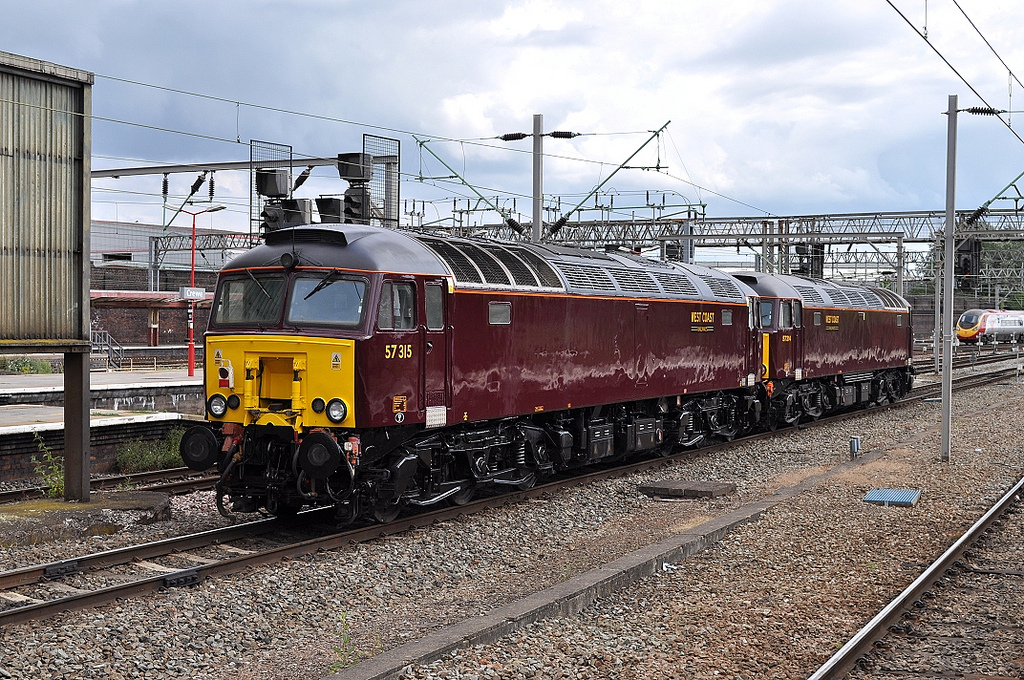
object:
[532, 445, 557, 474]
wheel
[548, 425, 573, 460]
wheel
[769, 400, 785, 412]
wheel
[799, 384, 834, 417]
wheel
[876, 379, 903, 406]
wheel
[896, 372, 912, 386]
wheel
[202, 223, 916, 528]
train